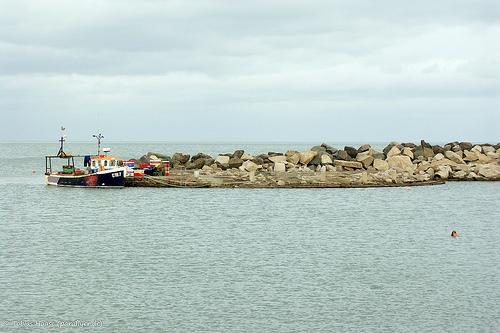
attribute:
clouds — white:
[191, 48, 348, 100]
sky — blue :
[1, 8, 498, 143]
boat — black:
[44, 168, 129, 190]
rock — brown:
[190, 153, 212, 168]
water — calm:
[32, 198, 494, 295]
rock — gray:
[376, 151, 421, 175]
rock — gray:
[331, 152, 366, 171]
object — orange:
[448, 227, 458, 239]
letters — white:
[108, 168, 123, 179]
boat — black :
[37, 126, 164, 188]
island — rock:
[133, 138, 499, 190]